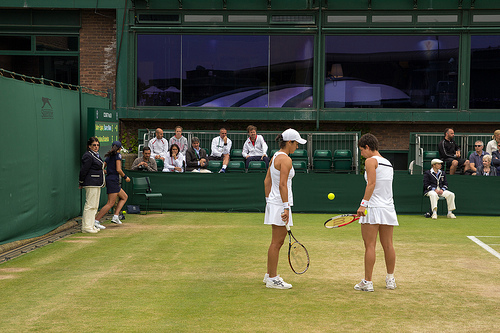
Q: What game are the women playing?
A: Tennis.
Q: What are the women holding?
A: Tennis rackets.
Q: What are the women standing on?
A: Grass.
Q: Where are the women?
A: On a tennis court.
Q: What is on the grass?
A: White lines.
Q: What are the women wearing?
A: Tennis outfits.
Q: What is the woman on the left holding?
A: A tennis racket.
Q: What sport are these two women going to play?
A: Tennis.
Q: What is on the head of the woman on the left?
A: A white hat.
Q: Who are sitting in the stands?
A: Spectators.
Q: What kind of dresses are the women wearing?
A: Sport dresses.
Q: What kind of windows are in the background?
A: Tinted.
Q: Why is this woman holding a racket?
A: She's going to play tennis.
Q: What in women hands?
A: Tennis racket.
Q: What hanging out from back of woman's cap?
A: Woman's hair.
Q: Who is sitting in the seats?
A: Tennis fans.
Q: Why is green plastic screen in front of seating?
A: Protect the fans.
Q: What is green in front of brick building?
A: Wood glass frame.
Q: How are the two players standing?
A: Facing each other.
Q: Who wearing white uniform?
A: Two tennis players.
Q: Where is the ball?
A: In the air.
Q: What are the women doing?
A: Playing tennis.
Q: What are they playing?
A: Tennis.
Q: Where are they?
A: A tennis court.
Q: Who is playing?
A: Two women.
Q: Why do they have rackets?
A: To hit the ball.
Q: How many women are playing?
A: Two.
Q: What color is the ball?
A: Green.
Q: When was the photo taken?
A: Afternoon.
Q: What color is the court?
A: Green and brown.